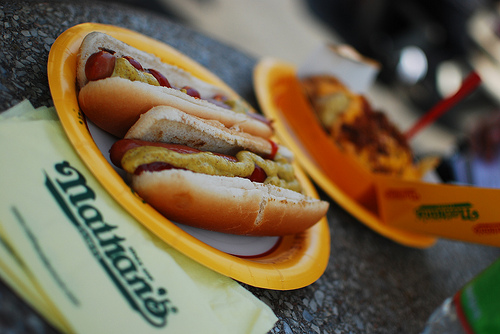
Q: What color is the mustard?
A: Yellow.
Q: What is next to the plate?
A: Napkins.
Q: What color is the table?
A: Gray.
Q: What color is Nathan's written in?
A: Green.